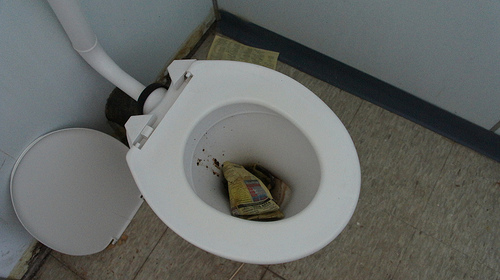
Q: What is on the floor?
A: Tiles.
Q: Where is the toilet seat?
A: On the floor.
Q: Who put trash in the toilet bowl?
A: Unabe to determine.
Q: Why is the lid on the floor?
A: It is broken.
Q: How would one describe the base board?
A: Dark colored.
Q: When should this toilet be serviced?
A: Now.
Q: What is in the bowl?
A: Trash.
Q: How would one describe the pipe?
A: White.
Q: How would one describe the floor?
A: Covered with tan and white tiles.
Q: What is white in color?
A: A toilet.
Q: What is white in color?
A: A toilet.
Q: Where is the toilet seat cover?
A: It is on the ground.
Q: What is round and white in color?
A: A toilet seat.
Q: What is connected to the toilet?
A: A white long pipe.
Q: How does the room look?
A: It is a tiled room.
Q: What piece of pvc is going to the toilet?
A: Water pipe.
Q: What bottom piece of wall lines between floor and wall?
A: Trim.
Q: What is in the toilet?
A: Paper.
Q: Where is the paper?
A: In the toilet.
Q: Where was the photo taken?
A: In bathroom.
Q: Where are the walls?
A: Next to toilet.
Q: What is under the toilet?
A: Floor.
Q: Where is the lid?
A: On the floor.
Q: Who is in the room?
A: No people.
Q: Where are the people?
A: None in photo.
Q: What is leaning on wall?
A: Lid.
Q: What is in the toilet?
A: Paper.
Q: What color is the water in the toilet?
A: Brown.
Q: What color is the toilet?
A: White.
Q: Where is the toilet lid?
A: Beside the toilet.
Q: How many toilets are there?
A: 1.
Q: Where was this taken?
A: Bathroom.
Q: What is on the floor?
A: Tile.